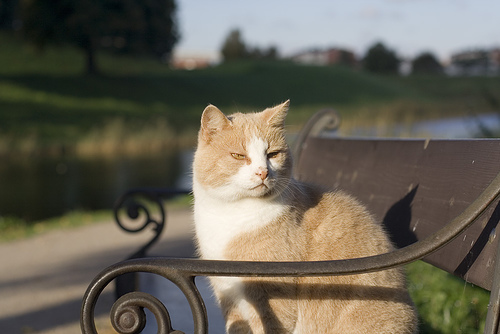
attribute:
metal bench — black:
[98, 136, 493, 321]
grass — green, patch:
[423, 286, 472, 327]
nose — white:
[249, 148, 277, 182]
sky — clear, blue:
[174, 1, 496, 56]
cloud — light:
[357, 6, 381, 23]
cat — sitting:
[189, 107, 372, 244]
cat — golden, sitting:
[190, 94, 423, 332]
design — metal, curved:
[70, 251, 212, 331]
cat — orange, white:
[114, 70, 429, 332]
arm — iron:
[79, 252, 199, 332]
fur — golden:
[321, 206, 366, 238]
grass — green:
[133, 75, 329, 100]